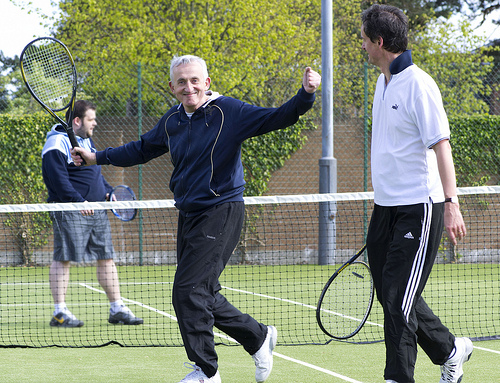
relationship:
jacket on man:
[83, 97, 317, 203] [55, 57, 305, 379]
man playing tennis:
[66, 52, 323, 381] [17, 30, 90, 170]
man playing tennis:
[350, 5, 477, 383] [17, 30, 90, 170]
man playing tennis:
[42, 96, 144, 328] [17, 30, 90, 170]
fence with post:
[0, 58, 498, 265] [131, 56, 375, 269]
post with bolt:
[307, 2, 348, 269] [324, 207, 336, 225]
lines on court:
[65, 272, 427, 375] [14, 14, 497, 371]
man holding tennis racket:
[66, 52, 323, 381] [14, 37, 101, 160]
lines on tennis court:
[257, 288, 367, 329] [1, 180, 484, 381]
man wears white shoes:
[71, 47, 329, 381] [182, 339, 293, 381]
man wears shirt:
[71, 47, 329, 381] [127, 67, 323, 198]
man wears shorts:
[36, 93, 140, 332] [43, 198, 115, 262]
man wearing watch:
[350, 5, 470, 380] [440, 195, 462, 204]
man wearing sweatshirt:
[66, 52, 323, 381] [11, 36, 93, 141]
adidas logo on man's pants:
[399, 228, 414, 242] [360, 200, 452, 381]